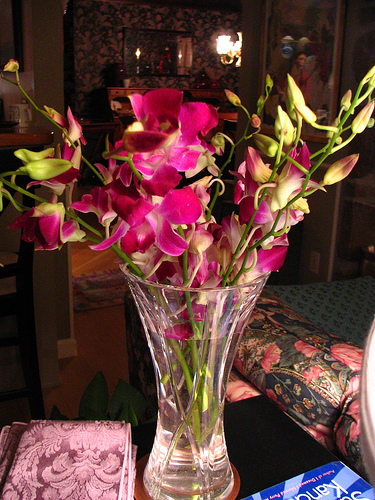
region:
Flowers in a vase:
[0, 60, 374, 498]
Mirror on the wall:
[120, 24, 194, 77]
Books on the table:
[1, 418, 138, 498]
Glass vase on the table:
[122, 263, 272, 498]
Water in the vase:
[143, 334, 237, 499]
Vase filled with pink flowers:
[3, 56, 373, 498]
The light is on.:
[215, 29, 250, 70]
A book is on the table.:
[241, 457, 372, 498]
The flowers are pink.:
[13, 86, 309, 279]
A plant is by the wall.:
[49, 376, 156, 424]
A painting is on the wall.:
[250, 1, 336, 145]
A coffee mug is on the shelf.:
[6, 99, 33, 127]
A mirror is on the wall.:
[120, 24, 197, 78]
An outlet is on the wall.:
[307, 247, 322, 276]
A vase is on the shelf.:
[112, 62, 128, 86]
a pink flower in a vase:
[118, 88, 224, 187]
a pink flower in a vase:
[45, 103, 91, 168]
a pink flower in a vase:
[17, 191, 67, 246]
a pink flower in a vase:
[117, 188, 208, 271]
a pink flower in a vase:
[230, 223, 296, 269]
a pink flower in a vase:
[264, 138, 317, 207]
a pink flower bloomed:
[106, 195, 222, 272]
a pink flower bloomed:
[29, 197, 80, 258]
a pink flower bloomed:
[246, 158, 291, 210]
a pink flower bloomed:
[126, 83, 213, 180]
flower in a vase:
[330, 94, 369, 124]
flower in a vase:
[240, 152, 281, 192]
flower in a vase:
[162, 182, 197, 228]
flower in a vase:
[192, 103, 243, 144]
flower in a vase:
[153, 220, 183, 265]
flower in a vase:
[129, 172, 159, 198]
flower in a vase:
[79, 180, 114, 217]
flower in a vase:
[18, 202, 67, 244]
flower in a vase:
[55, 106, 90, 155]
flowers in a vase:
[99, 55, 281, 476]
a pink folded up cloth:
[0, 420, 128, 498]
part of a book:
[244, 459, 373, 499]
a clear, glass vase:
[120, 271, 273, 498]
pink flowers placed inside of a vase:
[4, 57, 373, 428]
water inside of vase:
[146, 328, 240, 494]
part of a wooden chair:
[1, 176, 47, 417]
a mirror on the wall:
[121, 31, 195, 74]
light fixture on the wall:
[216, 32, 242, 66]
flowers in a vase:
[332, 75, 368, 120]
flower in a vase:
[273, 90, 296, 139]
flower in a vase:
[270, 182, 310, 213]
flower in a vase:
[230, 190, 265, 224]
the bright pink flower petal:
[158, 186, 203, 222]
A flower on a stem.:
[23, 200, 89, 252]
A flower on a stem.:
[119, 189, 209, 268]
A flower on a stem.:
[136, 141, 194, 189]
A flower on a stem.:
[133, 81, 188, 145]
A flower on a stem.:
[327, 151, 369, 197]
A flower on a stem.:
[253, 238, 305, 277]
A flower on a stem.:
[240, 198, 286, 223]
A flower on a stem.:
[219, 207, 260, 247]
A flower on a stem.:
[20, 157, 92, 177]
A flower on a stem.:
[22, 198, 100, 254]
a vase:
[129, 284, 237, 482]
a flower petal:
[166, 194, 191, 229]